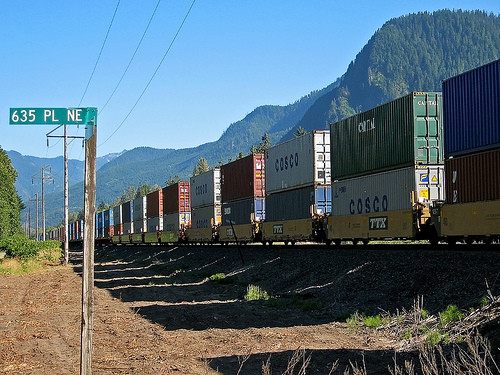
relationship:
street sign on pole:
[11, 107, 96, 123] [81, 132, 97, 374]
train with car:
[38, 58, 500, 247] [435, 62, 497, 247]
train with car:
[38, 58, 500, 247] [319, 83, 442, 248]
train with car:
[38, 58, 500, 247] [260, 120, 329, 240]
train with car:
[38, 58, 500, 247] [220, 143, 260, 243]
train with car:
[38, 58, 500, 247] [184, 160, 216, 245]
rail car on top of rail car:
[331, 97, 449, 167] [327, 176, 438, 208]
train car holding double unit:
[159, 229, 189, 244] [164, 181, 191, 226]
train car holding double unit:
[259, 127, 331, 243] [146, 191, 167, 233]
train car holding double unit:
[131, 230, 143, 242] [130, 200, 148, 231]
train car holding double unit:
[120, 235, 131, 245] [119, 199, 136, 237]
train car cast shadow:
[433, 49, 497, 239] [63, 239, 170, 264]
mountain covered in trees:
[265, 8, 498, 144] [318, 4, 496, 134]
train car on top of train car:
[217, 153, 267, 202] [220, 196, 267, 229]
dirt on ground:
[0, 264, 382, 374] [2, 239, 499, 373]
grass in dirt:
[435, 301, 467, 327] [0, 264, 382, 374]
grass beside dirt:
[2, 235, 64, 277] [0, 264, 382, 374]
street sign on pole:
[7, 105, 98, 126] [82, 131, 93, 373]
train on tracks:
[36, 58, 498, 248] [95, 235, 499, 262]